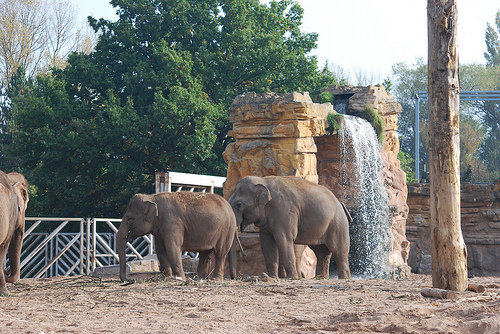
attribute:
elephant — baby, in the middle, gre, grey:
[109, 182, 239, 279]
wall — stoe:
[381, 185, 499, 268]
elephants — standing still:
[116, 162, 352, 276]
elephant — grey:
[230, 172, 355, 280]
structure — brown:
[211, 84, 414, 273]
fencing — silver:
[24, 210, 144, 267]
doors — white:
[14, 185, 159, 272]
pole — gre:
[404, 86, 425, 183]